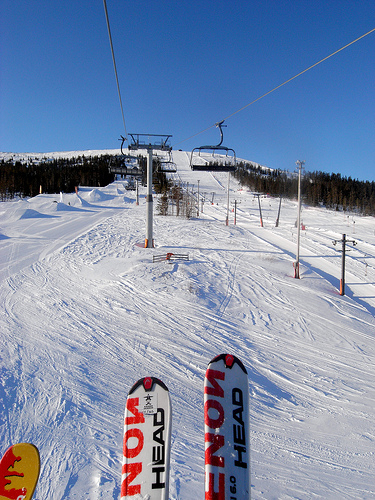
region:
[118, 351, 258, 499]
edge of skis with writing on them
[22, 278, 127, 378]
skiing tracks crisscrossing a slope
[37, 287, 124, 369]
snowy slope that has been skied on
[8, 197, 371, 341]
snow covered skiing slope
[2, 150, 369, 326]
snow covered hill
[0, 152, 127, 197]
large stand of densely growing trees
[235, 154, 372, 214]
forest of trees growing along a skiing slope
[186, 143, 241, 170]
ski lift heading down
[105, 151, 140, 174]
ski lift heading up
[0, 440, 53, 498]
edge of yellow skis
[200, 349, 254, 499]
a board on top of snow.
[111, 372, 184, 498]
a left ski on the snow.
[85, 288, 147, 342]
tracks left in snow.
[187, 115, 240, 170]
a ski lift.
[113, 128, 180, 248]
a tall ski lift support.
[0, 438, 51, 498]
a red and yellow ski.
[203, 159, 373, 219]
a forest of green trees.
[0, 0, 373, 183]
a clear blue sky.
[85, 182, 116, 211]
a small hill made out of snow.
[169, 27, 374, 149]
a wire above a ski slope.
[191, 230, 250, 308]
this is a footprint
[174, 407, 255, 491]
this is a ski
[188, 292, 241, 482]
the ski is white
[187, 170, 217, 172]
this is a chair lift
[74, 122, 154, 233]
this is a ski slope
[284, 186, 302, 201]
this is a pole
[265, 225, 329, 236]
the pole is metal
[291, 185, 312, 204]
the pole is silver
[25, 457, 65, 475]
the ski is yellow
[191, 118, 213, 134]
there are no clouds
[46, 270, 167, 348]
A large body of snow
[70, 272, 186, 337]
A large body of white snow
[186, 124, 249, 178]
A ski lift in the distance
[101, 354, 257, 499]
Two skis with a black tip top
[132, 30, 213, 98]
No clouds in the sky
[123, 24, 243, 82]
Large body of blue skies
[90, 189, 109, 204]
Snow ramp in the distance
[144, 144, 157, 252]
Tall and large pole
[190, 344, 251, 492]
ski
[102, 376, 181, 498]
ski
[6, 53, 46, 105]
white clouds in blue sky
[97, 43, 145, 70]
white clouds in blue sky